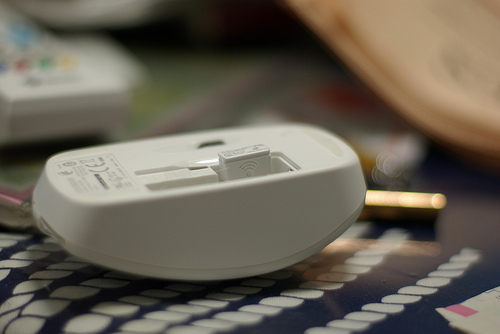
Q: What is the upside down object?
A: Mouse.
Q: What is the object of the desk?
A: A computer mouse.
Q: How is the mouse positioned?
A: It is upside down.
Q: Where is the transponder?
A: Protruding from the center.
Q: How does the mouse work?
A: Wirelessly.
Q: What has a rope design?
A: Blue cloth.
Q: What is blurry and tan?
A: The object.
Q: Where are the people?
A: None in photo.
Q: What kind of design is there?
A: White rope.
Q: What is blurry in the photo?
A: The background.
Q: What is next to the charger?
A: Blurry item.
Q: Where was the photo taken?
A: Next to a desk.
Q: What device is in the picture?
A: Mouse.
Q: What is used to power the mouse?
A: Battery.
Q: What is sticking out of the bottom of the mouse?
A: A wireless receiver.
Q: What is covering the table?
A: A cloth.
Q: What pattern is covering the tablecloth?
A: Round white squares.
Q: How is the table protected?
A: By a table cloth.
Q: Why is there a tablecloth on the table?
A: To protect it.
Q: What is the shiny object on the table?
A: A battery.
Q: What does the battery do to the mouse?
A: Power it.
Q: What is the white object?
A: Upside down computer mouse.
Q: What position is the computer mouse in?
A: Upside down.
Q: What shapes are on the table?
A: Small white squares.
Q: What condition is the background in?
A: Blurred.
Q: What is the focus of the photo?
A: Upside down mouse.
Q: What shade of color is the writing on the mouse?
A: Grey.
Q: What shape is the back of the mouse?
A: Curved.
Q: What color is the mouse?
A: White.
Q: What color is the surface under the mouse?
A: Blue and white.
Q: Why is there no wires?
A: Wireless.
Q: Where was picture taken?
A: At a desk.